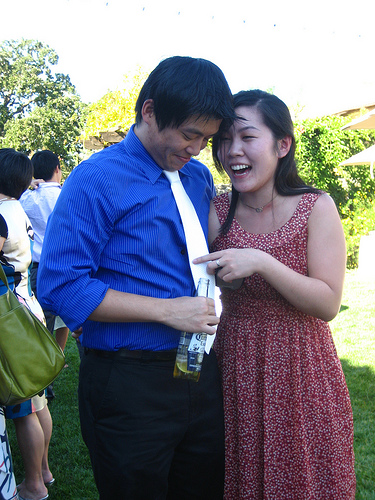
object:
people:
[192, 88, 345, 499]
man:
[36, 56, 223, 499]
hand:
[192, 248, 258, 281]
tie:
[165, 168, 219, 355]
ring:
[215, 260, 220, 265]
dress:
[214, 192, 353, 499]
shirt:
[37, 122, 213, 352]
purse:
[0, 290, 66, 408]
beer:
[173, 352, 201, 382]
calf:
[34, 419, 45, 460]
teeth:
[231, 165, 249, 171]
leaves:
[0, 38, 79, 154]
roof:
[291, 71, 375, 123]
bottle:
[173, 278, 209, 381]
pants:
[78, 349, 225, 499]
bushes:
[341, 196, 375, 270]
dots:
[291, 252, 293, 255]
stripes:
[147, 205, 150, 255]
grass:
[327, 278, 374, 500]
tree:
[295, 118, 348, 218]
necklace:
[238, 194, 279, 212]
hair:
[135, 55, 235, 131]